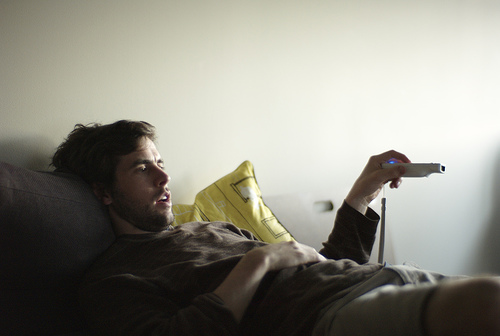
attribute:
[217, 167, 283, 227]
pillow — yellow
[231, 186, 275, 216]
pillow — yellow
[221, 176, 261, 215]
pillow — yellow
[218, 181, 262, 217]
pillow — yellow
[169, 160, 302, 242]
yellow pillow — on the bed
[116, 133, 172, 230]
man's face — bored